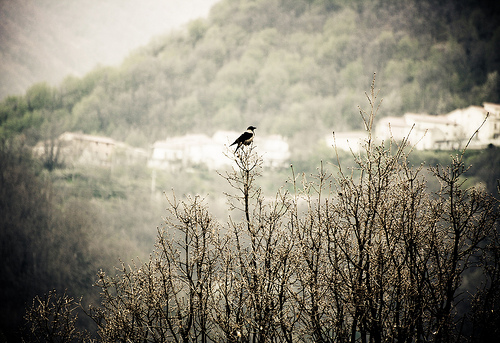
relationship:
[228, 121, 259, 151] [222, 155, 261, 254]
bird on branch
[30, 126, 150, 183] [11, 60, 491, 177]
building on hillside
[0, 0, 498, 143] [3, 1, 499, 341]
trees on hillside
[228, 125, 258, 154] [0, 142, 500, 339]
bird on tree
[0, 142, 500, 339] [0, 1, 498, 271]
tree near hillside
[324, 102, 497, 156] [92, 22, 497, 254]
building on hillside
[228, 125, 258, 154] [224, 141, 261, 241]
bird on branch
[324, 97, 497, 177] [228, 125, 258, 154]
building behind bird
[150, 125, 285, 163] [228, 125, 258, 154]
building behind bird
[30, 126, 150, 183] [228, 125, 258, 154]
building behind bird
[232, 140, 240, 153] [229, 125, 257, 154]
tail on bird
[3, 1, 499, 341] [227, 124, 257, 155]
hillside behind bird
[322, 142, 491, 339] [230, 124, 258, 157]
tree under bird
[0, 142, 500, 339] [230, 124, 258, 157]
tree under bird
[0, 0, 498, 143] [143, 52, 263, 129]
trees in forest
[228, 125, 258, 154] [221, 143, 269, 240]
bird pirched atop branch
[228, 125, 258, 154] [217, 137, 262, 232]
bird on branch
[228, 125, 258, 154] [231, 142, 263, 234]
bird on branch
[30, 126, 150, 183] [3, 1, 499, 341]
building on hillside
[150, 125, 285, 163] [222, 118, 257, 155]
building and bird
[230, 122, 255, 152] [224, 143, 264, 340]
corvide on branch